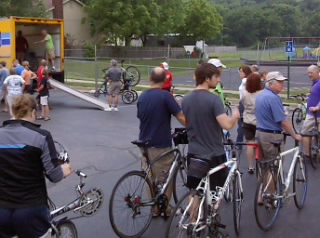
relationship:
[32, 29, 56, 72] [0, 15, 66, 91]
man in truck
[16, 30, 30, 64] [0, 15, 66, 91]
man in truck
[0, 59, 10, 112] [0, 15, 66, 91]
man beside truck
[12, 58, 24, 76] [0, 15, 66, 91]
man near truck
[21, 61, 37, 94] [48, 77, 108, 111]
girl near truck ramp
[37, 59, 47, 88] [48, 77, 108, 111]
man near truck ramp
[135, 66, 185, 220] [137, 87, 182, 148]
man wearing shirt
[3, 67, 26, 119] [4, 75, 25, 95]
man wearing shirt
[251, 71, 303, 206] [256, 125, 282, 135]
man wearing belt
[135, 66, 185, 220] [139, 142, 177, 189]
man wearing shorts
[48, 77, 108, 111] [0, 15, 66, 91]
ramp to truck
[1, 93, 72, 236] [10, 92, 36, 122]
woman has hair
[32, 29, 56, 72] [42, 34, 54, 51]
man wearing shirt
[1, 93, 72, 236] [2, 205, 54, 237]
woman wearing shorts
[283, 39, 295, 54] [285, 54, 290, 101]
sign on pole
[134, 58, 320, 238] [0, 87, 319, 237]
people in parking lot